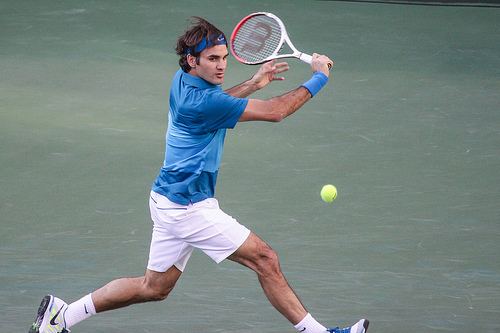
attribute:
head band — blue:
[186, 33, 230, 57]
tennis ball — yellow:
[319, 184, 339, 203]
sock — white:
[66, 294, 96, 330]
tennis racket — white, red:
[232, 10, 316, 66]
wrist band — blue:
[301, 71, 326, 97]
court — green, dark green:
[0, 1, 496, 332]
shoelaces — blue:
[328, 330, 352, 332]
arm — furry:
[225, 56, 289, 97]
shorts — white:
[147, 189, 252, 273]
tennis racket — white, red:
[228, 0, 332, 70]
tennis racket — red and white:
[230, 11, 312, 65]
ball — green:
[314, 182, 346, 206]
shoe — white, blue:
[27, 291, 69, 331]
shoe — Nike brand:
[30, 295, 67, 332]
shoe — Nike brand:
[328, 317, 369, 331]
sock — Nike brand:
[294, 312, 326, 332]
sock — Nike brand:
[65, 292, 97, 327]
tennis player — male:
[94, 7, 388, 316]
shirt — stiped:
[144, 70, 245, 207]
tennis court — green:
[48, 31, 468, 328]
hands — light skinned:
[238, 46, 283, 81]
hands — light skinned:
[294, 44, 369, 123]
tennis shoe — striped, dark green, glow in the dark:
[28, 291, 68, 331]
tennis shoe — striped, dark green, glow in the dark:
[327, 310, 365, 330]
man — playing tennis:
[33, 40, 402, 322]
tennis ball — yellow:
[314, 176, 341, 211]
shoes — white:
[17, 280, 104, 332]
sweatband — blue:
[179, 28, 228, 58]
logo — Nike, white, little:
[209, 34, 223, 41]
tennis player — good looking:
[65, 13, 368, 331]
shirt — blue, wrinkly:
[151, 68, 250, 204]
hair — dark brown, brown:
[175, 15, 227, 73]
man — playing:
[29, 15, 369, 332]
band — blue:
[188, 36, 226, 53]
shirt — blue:
[154, 92, 251, 207]